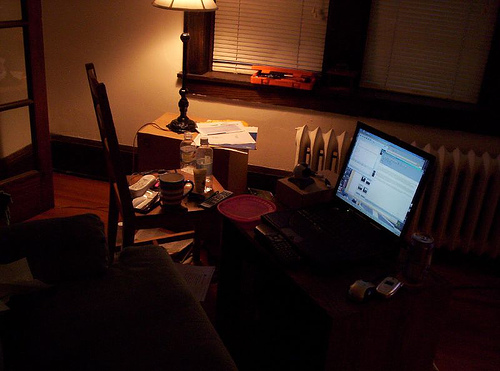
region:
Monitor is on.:
[317, 105, 440, 264]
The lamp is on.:
[142, 0, 225, 137]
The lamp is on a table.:
[149, 1, 211, 149]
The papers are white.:
[187, 108, 264, 165]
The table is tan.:
[135, 85, 267, 193]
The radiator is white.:
[280, 103, 491, 200]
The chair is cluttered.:
[117, 129, 240, 234]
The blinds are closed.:
[210, 2, 332, 104]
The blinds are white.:
[205, 1, 325, 86]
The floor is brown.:
[34, 145, 127, 237]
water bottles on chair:
[175, 126, 220, 181]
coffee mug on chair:
[155, 165, 195, 206]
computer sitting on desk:
[342, 122, 432, 255]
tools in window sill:
[244, 51, 337, 89]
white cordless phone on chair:
[129, 165, 155, 193]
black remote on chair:
[199, 184, 231, 211]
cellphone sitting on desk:
[376, 263, 405, 306]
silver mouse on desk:
[345, 270, 375, 312]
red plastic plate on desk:
[214, 178, 272, 235]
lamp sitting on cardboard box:
[163, 0, 218, 138]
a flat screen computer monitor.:
[329, 113, 438, 248]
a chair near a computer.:
[69, 54, 303, 271]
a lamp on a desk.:
[141, 0, 223, 134]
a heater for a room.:
[289, 120, 492, 232]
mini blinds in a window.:
[209, 0, 320, 89]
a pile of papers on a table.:
[175, 108, 288, 170]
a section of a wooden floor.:
[76, 179, 90, 199]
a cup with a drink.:
[134, 156, 204, 225]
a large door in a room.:
[1, 3, 66, 216]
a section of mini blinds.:
[215, 31, 323, 50]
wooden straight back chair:
[61, 53, 231, 298]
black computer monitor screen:
[325, 110, 439, 310]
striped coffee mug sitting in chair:
[152, 165, 197, 220]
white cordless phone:
[125, 164, 158, 199]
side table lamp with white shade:
[139, 0, 221, 139]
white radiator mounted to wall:
[274, 106, 498, 226]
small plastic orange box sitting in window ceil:
[245, 58, 332, 100]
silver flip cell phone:
[380, 268, 412, 305]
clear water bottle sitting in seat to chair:
[190, 131, 218, 198]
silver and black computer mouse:
[343, 271, 380, 303]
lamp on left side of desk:
[153, 1, 221, 138]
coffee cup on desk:
[156, 175, 185, 222]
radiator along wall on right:
[278, 118, 493, 173]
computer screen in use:
[338, 127, 424, 252]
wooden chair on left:
[85, 74, 215, 262]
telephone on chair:
[125, 172, 155, 195]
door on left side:
[15, 5, 48, 225]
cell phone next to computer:
[375, 276, 408, 302]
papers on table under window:
[198, 120, 250, 148]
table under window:
[144, 110, 263, 176]